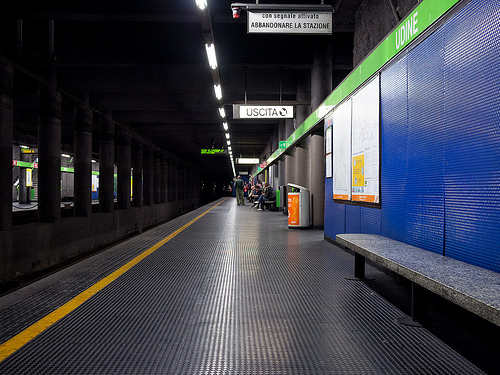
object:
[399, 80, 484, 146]
wall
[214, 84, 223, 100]
light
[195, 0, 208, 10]
light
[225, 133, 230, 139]
light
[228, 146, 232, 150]
light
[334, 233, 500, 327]
bench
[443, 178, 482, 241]
wall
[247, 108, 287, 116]
black letter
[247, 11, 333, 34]
signs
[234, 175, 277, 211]
people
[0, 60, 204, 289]
subway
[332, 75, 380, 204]
map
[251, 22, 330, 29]
letter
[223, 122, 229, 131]
light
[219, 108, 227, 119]
light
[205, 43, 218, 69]
light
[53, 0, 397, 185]
ceiling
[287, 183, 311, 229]
trashcan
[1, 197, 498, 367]
train platform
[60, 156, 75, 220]
window